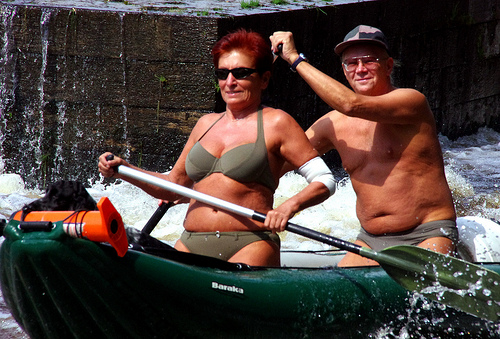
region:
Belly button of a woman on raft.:
[209, 203, 217, 213]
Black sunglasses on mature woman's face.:
[216, 65, 266, 78]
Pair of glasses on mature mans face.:
[340, 51, 392, 68]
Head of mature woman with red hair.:
[213, 29, 270, 105]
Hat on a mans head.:
[332, 22, 387, 56]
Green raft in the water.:
[0, 218, 499, 337]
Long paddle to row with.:
[106, 152, 498, 326]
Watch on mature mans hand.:
[291, 53, 304, 69]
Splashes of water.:
[402, 272, 457, 331]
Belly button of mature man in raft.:
[371, 207, 393, 220]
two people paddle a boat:
[4, 17, 480, 322]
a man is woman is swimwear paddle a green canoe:
[8, 6, 498, 289]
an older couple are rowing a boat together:
[5, 3, 491, 329]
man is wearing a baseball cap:
[330, 18, 400, 53]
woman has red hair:
[209, 32, 283, 76]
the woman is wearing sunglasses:
[208, 58, 273, 84]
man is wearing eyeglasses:
[339, 51, 387, 73]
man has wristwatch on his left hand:
[289, 47, 306, 75]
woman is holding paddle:
[92, 170, 494, 327]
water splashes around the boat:
[369, 258, 487, 332]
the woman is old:
[175, 29, 287, 266]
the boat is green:
[9, 190, 436, 335]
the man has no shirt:
[287, 26, 479, 252]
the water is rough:
[28, 148, 214, 256]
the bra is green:
[168, 102, 290, 201]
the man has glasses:
[323, 44, 410, 85]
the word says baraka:
[200, 267, 274, 314]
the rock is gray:
[74, 18, 168, 112]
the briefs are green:
[341, 213, 468, 264]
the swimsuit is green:
[167, 208, 279, 273]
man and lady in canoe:
[132, 27, 492, 322]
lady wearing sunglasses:
[202, 26, 295, 128]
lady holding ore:
[89, 119, 360, 309]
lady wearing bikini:
[139, 7, 335, 317]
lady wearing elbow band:
[287, 128, 382, 263]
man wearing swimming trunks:
[267, 14, 498, 282]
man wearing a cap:
[301, 12, 416, 132]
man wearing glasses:
[310, 26, 423, 113]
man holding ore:
[263, 18, 331, 95]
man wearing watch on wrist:
[276, 27, 333, 114]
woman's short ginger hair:
[207, 20, 265, 52]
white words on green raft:
[184, 268, 264, 298]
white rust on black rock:
[10, 32, 131, 139]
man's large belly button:
[356, 197, 418, 227]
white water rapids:
[318, 202, 352, 222]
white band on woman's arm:
[280, 139, 342, 215]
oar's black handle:
[69, 138, 136, 195]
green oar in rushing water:
[349, 234, 499, 333]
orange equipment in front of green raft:
[10, 196, 135, 280]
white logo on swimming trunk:
[431, 220, 454, 245]